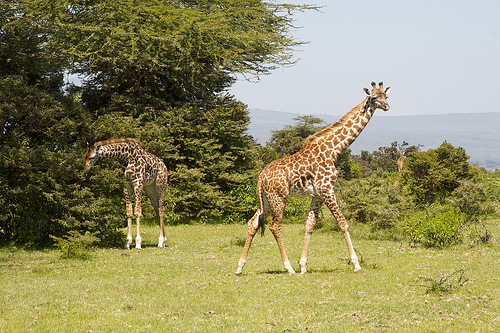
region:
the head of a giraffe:
[354, 65, 416, 130]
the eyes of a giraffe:
[363, 60, 439, 108]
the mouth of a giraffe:
[368, 86, 410, 113]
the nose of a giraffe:
[374, 95, 400, 120]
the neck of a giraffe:
[307, 100, 387, 183]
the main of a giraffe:
[296, 95, 383, 157]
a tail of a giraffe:
[242, 143, 319, 244]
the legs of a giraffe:
[237, 143, 410, 276]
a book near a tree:
[63, 128, 205, 259]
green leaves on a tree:
[103, 38, 193, 125]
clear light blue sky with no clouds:
[6, 2, 497, 119]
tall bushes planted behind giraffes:
[0, 90, 492, 250]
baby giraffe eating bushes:
[83, 132, 180, 262]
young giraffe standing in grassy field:
[236, 81, 401, 282]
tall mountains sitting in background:
[3, 104, 497, 174]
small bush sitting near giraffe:
[404, 207, 465, 248]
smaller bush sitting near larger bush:
[51, 227, 98, 258]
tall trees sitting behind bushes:
[0, 0, 290, 100]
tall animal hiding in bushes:
[394, 151, 408, 173]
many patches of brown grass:
[166, 277, 492, 329]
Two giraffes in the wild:
[65, 69, 394, 289]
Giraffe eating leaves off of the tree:
[84, 138, 174, 255]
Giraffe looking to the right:
[230, 75, 414, 282]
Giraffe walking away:
[235, 76, 393, 277]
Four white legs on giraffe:
[235, 242, 367, 279]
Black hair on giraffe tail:
[252, 208, 274, 238]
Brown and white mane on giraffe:
[299, 85, 380, 157]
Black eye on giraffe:
[370, 92, 379, 108]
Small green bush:
[409, 256, 471, 307]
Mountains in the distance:
[228, 83, 498, 199]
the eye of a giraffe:
[366, 94, 381, 111]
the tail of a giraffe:
[236, 174, 291, 276]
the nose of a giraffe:
[367, 100, 407, 116]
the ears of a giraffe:
[357, 65, 425, 110]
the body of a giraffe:
[234, 137, 356, 252]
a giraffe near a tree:
[71, 100, 212, 265]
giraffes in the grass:
[65, 83, 390, 272]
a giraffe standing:
[236, 80, 392, 268]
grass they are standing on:
[27, 275, 490, 324]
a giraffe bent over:
[83, 141, 168, 241]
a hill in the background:
[251, 102, 498, 161]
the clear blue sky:
[307, 8, 481, 60]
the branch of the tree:
[9, 8, 319, 83]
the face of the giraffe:
[360, 80, 398, 112]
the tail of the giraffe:
[253, 178, 269, 231]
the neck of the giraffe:
[331, 111, 372, 151]